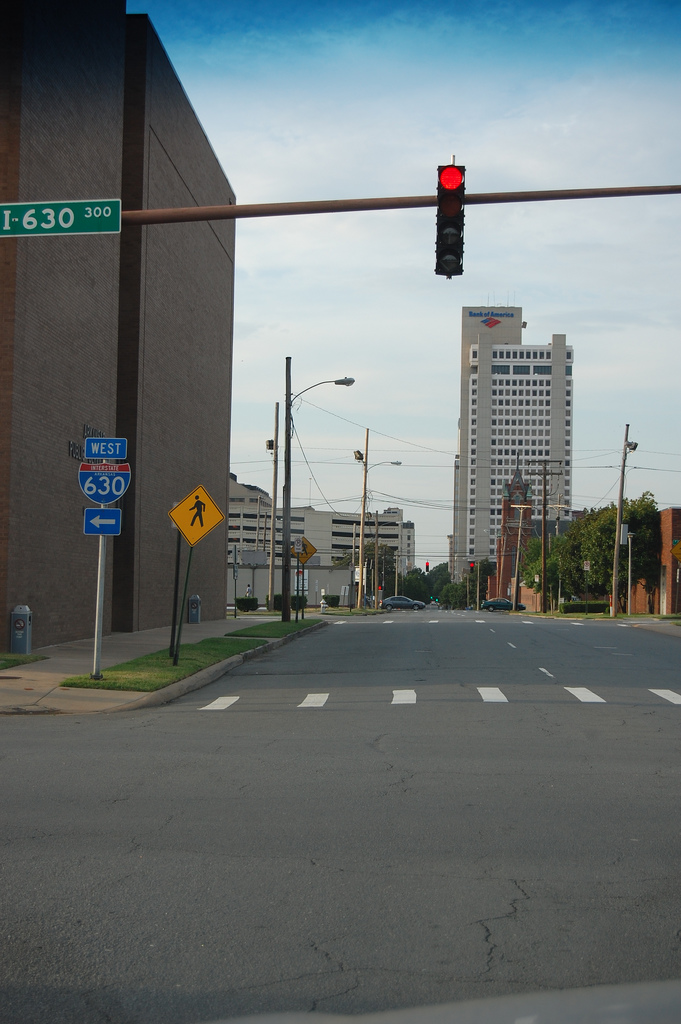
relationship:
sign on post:
[71, 416, 146, 546] [68, 423, 193, 756]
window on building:
[510, 364, 534, 392] [456, 286, 609, 624]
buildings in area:
[11, 87, 618, 618] [244, 641, 655, 1001]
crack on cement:
[472, 891, 532, 982] [253, 820, 647, 1015]